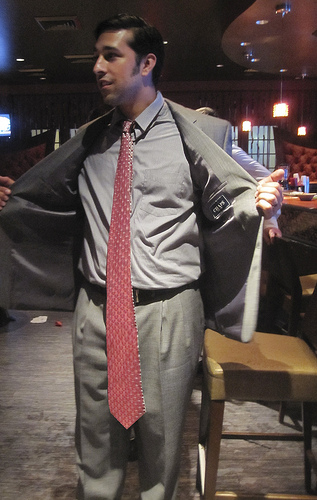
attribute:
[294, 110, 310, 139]
light — on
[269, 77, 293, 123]
light — on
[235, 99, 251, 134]
light — on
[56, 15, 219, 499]
man — standing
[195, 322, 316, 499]
stool — empty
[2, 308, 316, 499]
floor — dirty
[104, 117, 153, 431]
necktie — long, pinkish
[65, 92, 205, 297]
shirt — gray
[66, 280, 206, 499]
pants — gray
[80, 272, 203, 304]
belt — black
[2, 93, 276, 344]
jacket — gray, open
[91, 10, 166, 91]
hair — dark, groomed, parted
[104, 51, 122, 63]
eye — open